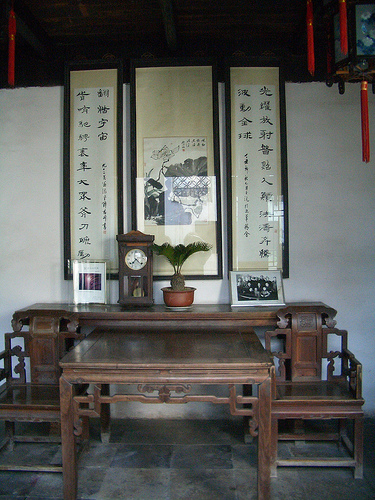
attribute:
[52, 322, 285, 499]
table — vintage, tall, old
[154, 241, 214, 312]
plant — small, potted, green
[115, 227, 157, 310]
clock — old, wooden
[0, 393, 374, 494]
floor — tiled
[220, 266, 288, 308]
photo — old, framed, black, white, rectangular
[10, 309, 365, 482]
chair — japanese, wooden, facing, backed, seated, fading, old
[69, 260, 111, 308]
picture — framed, reflecting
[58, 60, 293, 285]
art — framed, hanging, tall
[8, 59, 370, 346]
wall — white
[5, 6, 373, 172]
tassels — hanging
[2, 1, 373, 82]
ceiling — wooden, lit